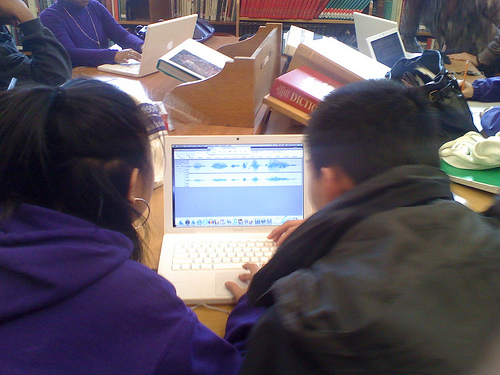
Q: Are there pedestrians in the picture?
A: No, there are no pedestrians.